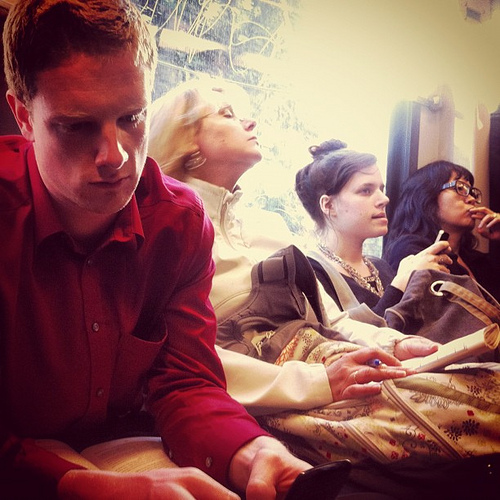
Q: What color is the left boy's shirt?
A: Red.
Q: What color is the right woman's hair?
A: Black.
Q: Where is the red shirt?
A: On the boy.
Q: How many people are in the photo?
A: Four.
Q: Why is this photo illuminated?
A: Sunlight.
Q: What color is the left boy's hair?
A: Brown.